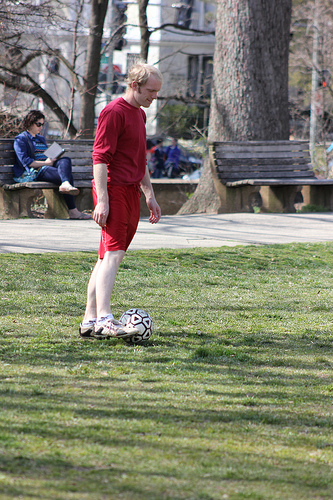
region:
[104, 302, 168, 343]
Soccer ball on the ground.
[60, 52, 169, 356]
Man standing behind the soccer ball.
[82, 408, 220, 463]
The grass is green.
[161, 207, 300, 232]
Sidewalk is paved.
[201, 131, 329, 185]
Bench over the sidewalk.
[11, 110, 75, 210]
Woman sitting on a bench.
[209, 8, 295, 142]
Tree behind the bench.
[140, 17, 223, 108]
Building in the background.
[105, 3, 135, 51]
Back of a stoplight.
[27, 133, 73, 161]
Woman is reading a book.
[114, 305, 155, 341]
black and white soccer ball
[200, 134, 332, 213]
empty park bench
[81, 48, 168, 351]
blond man wearing red shirt and shorts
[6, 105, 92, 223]
woman reading a book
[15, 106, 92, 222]
woman wearing sunglasses in a park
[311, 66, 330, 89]
stoplight with a red light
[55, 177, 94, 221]
woman's feet, wearing sandals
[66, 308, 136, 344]
man's soccer cleats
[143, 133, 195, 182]
people in background, blurry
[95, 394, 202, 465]
green grass in park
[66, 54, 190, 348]
Soccer player kicking soccer ball.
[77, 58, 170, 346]
Soccer player wearing red shirt.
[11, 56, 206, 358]
Soccer player standing near bench.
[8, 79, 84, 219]
Woman sitting on bench.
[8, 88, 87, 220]
Woman sitting on bench reading book.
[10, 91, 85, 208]
Woman wearing jeans sitting on bench.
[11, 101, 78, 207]
Woman wearing glasses.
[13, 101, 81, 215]
Woman with dark hair sitting on bench.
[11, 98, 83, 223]
Woman wearing glasses reading a book.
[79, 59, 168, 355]
Soccer player wearing red shorts.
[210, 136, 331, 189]
An empty wooden park bench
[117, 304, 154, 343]
Soccer ball is white and black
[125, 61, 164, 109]
The man has blonde hair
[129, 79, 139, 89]
Man's ears are red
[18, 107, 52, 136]
A woman is wearing dark sunglasses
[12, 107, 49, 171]
Woman's jacket is blue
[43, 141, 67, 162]
A book is open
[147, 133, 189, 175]
A few people spending time together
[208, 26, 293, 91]
A very old tree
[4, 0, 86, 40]
The leaves have fallen from the tree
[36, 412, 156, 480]
A section of grass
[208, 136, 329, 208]
Bench in a park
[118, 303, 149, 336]
Medium-sized soccer ball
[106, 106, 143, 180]
The man's red shirt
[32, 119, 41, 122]
Sunglasses of the women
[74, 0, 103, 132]
Middle part of the tree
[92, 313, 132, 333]
Man's right white shoe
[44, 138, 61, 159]
Book the woman is reading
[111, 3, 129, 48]
Back of street light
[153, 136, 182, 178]
Two civilians talking